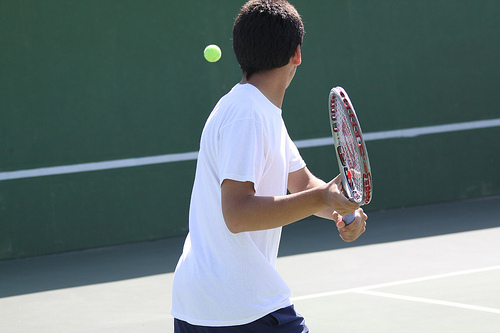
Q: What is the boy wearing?
A: A white t-shirt.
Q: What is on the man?
A: A white tee shirt.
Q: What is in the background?
A: A large green wall.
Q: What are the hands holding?
A: A tennis racket.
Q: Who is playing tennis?
A: A boy.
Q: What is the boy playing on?
A: A complete tennis court.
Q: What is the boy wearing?
A: A white tee shirt.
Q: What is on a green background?
A: A white stripe.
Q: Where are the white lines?
A: On the court.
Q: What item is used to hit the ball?
A: A racket.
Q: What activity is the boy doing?
A: Playing tennis.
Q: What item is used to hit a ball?
A: A racket.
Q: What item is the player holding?
A: A racket.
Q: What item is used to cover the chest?
A: A shirt.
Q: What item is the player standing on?
A: A court.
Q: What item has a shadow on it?
A: The court.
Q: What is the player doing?
A: Playing tennis.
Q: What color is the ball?
A: Yellow.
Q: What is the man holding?
A: A racket.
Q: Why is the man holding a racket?
A: The man is playing tennis.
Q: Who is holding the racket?
A: The man.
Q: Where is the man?
A: On a tennis court.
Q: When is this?
A: Daytime.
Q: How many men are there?
A: One.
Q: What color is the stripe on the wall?
A: White.